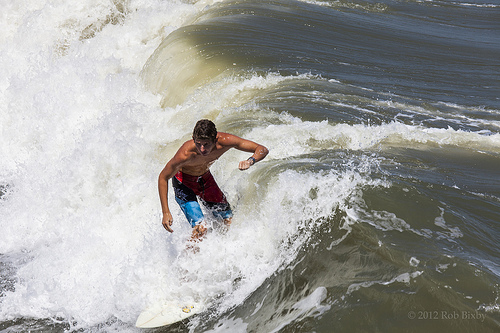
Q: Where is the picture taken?
A: On the ocean waves.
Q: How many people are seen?
A: One.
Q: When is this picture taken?
A: Daytime.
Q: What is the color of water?
A: Bluish grey.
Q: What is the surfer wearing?
A: Black and blue shorts.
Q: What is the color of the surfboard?
A: White.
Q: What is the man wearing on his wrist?
A: A wristband.